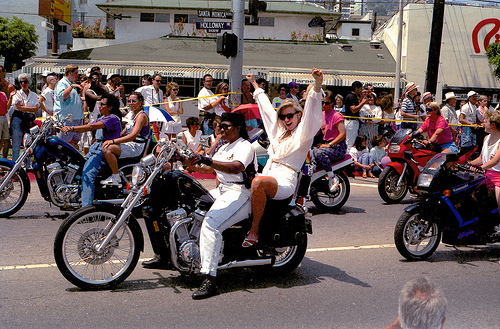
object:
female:
[240, 66, 325, 248]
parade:
[0, 0, 494, 323]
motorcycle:
[53, 138, 314, 290]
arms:
[300, 67, 327, 138]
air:
[3, 3, 214, 59]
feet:
[191, 275, 222, 301]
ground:
[0, 173, 500, 329]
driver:
[188, 110, 258, 300]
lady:
[408, 101, 460, 155]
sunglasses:
[426, 107, 437, 112]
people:
[8, 71, 41, 164]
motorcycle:
[377, 126, 481, 205]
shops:
[22, 33, 410, 78]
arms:
[54, 82, 84, 101]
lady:
[100, 91, 152, 187]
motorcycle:
[0, 113, 159, 219]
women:
[313, 96, 349, 193]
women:
[61, 92, 124, 208]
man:
[52, 62, 88, 144]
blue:
[52, 75, 86, 121]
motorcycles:
[245, 127, 354, 214]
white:
[255, 160, 299, 202]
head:
[0, 63, 9, 82]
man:
[0, 65, 16, 121]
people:
[342, 80, 367, 155]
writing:
[469, 17, 500, 57]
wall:
[408, 3, 500, 93]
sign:
[35, 0, 73, 26]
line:
[307, 244, 395, 252]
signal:
[215, 31, 238, 59]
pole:
[225, 0, 246, 110]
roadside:
[5, 0, 500, 169]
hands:
[311, 67, 325, 91]